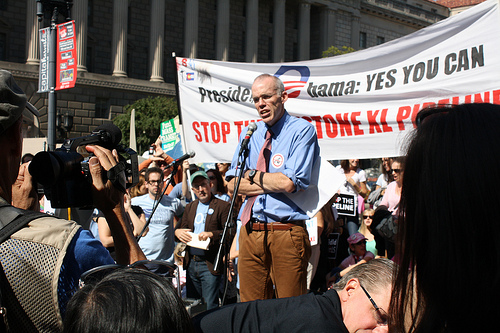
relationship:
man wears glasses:
[233, 78, 310, 302] [250, 92, 288, 107]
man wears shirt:
[233, 78, 310, 302] [233, 110, 323, 216]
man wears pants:
[233, 78, 310, 302] [236, 222, 307, 296]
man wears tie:
[233, 78, 310, 302] [240, 135, 270, 223]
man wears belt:
[233, 78, 310, 302] [245, 221, 299, 236]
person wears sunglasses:
[384, 164, 406, 215] [391, 167, 402, 173]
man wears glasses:
[129, 166, 180, 270] [147, 178, 163, 188]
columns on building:
[4, 3, 324, 92] [9, 2, 439, 152]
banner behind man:
[170, 1, 498, 162] [233, 78, 310, 302]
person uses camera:
[4, 67, 127, 326] [31, 123, 137, 216]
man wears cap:
[180, 169, 218, 306] [188, 171, 208, 177]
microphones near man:
[110, 123, 254, 262] [233, 78, 310, 302]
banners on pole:
[35, 28, 80, 93] [45, 91, 56, 149]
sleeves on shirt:
[219, 139, 307, 185] [233, 110, 323, 216]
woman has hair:
[404, 110, 500, 324] [401, 113, 499, 326]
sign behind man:
[170, 1, 498, 162] [233, 78, 310, 302]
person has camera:
[4, 67, 127, 326] [31, 123, 137, 216]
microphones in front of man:
[110, 123, 254, 262] [233, 78, 310, 302]